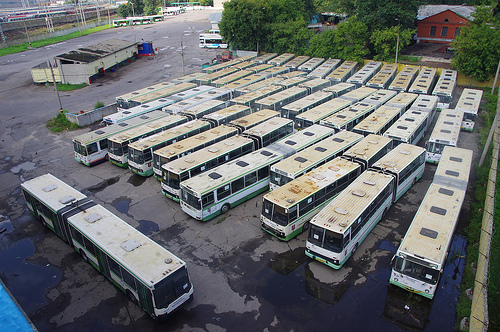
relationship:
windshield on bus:
[139, 266, 200, 314] [13, 177, 198, 326]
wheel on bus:
[220, 200, 240, 218] [169, 122, 334, 231]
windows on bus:
[213, 179, 232, 200] [17, 173, 194, 319]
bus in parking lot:
[17, 173, 194, 319] [9, 35, 485, 329]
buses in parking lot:
[192, 62, 429, 216] [9, 35, 485, 329]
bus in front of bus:
[17, 173, 194, 319] [180, 121, 331, 220]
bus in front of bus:
[17, 173, 194, 319] [166, 115, 327, 227]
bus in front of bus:
[17, 173, 194, 319] [253, 151, 365, 254]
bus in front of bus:
[17, 173, 194, 319] [17, 173, 194, 319]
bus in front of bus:
[17, 173, 194, 319] [424, 108, 463, 163]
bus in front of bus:
[17, 173, 194, 319] [157, 115, 333, 231]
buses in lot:
[57, 32, 409, 250] [11, 39, 498, 329]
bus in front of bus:
[180, 121, 331, 220] [318, 89, 397, 129]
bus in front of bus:
[357, 90, 419, 134] [398, 40, 458, 98]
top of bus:
[68, 202, 189, 283] [17, 173, 194, 319]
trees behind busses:
[217, 5, 419, 56] [68, 50, 483, 302]